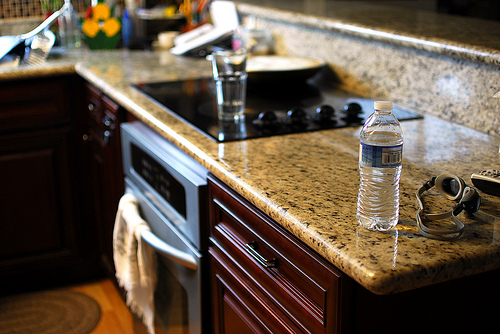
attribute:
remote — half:
[467, 162, 499, 188]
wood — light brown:
[73, 278, 135, 333]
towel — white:
[108, 185, 159, 332]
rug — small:
[17, 292, 98, 333]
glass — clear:
[206, 44, 251, 122]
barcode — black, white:
[380, 149, 403, 165]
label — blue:
[358, 142, 404, 168]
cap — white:
[373, 98, 394, 113]